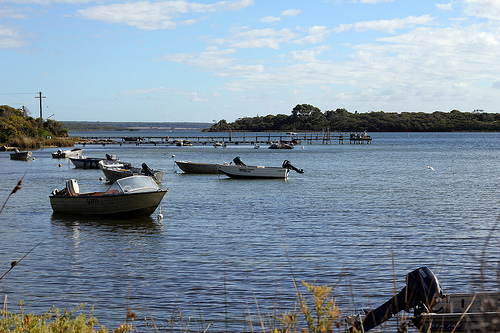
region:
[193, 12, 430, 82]
white clouds in the sky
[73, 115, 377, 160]
a wooden boat dock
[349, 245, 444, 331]
a black boat motor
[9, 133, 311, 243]
several boats in the water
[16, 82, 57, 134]
an wooden electrical pole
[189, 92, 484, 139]
trees growing in a row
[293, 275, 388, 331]
grass and weeds growing by the water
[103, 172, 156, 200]
a boats windshield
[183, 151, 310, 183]
a white boat with a black motor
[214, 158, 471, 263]
a large body of water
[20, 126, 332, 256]
a lot of parked boats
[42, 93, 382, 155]
dock for boat parking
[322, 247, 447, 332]
trolling motor for aluminum boat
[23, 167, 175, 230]
speed boat with wind shield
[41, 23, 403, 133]
cloudy bright blue sky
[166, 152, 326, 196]
two boats parked together in water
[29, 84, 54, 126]
electrical wire pole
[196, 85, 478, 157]
trees on a shoreline off the water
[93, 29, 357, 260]
boats in a lake on a bright day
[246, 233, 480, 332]
grass and weeds next to the lake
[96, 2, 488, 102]
partly cloudy blue sky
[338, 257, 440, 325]
outboard motor on a boat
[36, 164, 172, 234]
empty boat with buoy in the water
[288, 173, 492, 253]
calm water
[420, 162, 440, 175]
white bird flying over the water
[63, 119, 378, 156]
long wooden boat dock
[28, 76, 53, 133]
brown telephone pole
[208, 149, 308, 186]
small white fishing boat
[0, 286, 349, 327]
plants growing on the shore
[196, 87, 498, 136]
peninsula extending into the water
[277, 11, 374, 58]
white clouds in the sky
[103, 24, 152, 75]
blue sky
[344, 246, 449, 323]
a black outboard boat motor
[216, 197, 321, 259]
light choppiness on the water's surface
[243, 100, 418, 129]
deciduous trees with leaves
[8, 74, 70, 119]
power lines on a pole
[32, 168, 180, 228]
white boat in the water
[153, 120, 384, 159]
boat dock in the water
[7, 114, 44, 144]
green shrubs on a hill side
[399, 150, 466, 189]
a bird flying over the water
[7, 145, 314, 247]
Seven boat on the water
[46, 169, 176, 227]
Boat with a window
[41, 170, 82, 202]
Engine of boat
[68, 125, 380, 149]
Pier in a body of water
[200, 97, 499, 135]
Trees next to water body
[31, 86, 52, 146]
Electrical pole close to body water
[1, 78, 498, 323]
Boats in body water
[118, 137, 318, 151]
Boats next to pier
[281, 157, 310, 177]
Engine of white boat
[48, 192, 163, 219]
Hull of boat